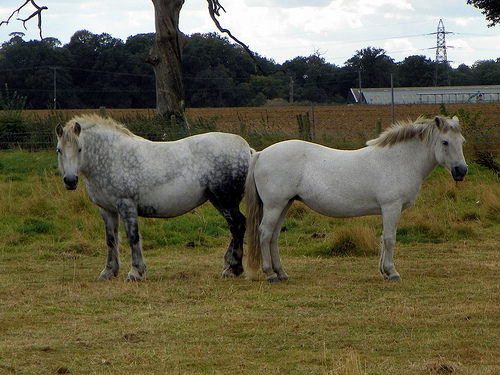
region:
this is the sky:
[379, 23, 400, 33]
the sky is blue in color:
[378, 20, 392, 32]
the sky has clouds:
[273, 10, 324, 59]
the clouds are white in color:
[258, 13, 288, 40]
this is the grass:
[104, 280, 219, 331]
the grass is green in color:
[141, 306, 211, 338]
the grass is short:
[165, 220, 188, 235]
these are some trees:
[195, 31, 407, 88]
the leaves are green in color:
[186, 43, 236, 85]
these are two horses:
[46, 117, 474, 350]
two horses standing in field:
[27, 63, 492, 374]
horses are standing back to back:
[25, 75, 485, 298]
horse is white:
[234, 105, 468, 288]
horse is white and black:
[42, 98, 249, 286]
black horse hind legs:
[189, 158, 258, 273]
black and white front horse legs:
[74, 183, 154, 285]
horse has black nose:
[57, 172, 82, 191]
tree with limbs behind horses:
[0, 8, 303, 263]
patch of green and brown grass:
[273, 195, 385, 269]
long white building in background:
[241, 48, 496, 122]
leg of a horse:
[100, 199, 127, 283]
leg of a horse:
[122, 203, 147, 280]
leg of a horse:
[221, 180, 248, 285]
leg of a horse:
[252, 192, 292, 284]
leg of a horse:
[375, 197, 407, 286]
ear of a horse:
[431, 110, 446, 134]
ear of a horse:
[67, 120, 84, 137]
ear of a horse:
[52, 118, 71, 140]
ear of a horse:
[448, 112, 460, 129]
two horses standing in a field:
[50, 92, 462, 307]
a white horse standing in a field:
[253, 111, 466, 276]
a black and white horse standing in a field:
[39, 103, 257, 288]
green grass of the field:
[211, 307, 358, 346]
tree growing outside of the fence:
[136, 0, 221, 120]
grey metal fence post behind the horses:
[305, 99, 322, 144]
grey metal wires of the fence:
[21, 62, 58, 147]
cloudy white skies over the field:
[288, 1, 359, 45]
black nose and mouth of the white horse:
[447, 158, 473, 188]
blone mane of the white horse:
[376, 119, 438, 146]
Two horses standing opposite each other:
[43, 113, 473, 292]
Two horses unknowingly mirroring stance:
[41, 100, 481, 309]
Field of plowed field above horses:
[13, 101, 495, 146]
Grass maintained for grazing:
[8, 164, 495, 365]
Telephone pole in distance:
[401, 18, 475, 98]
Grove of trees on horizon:
[0, 23, 491, 107]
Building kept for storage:
[338, 75, 498, 104]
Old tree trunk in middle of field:
[139, 0, 202, 137]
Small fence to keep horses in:
[0, 68, 490, 174]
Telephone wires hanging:
[6, 59, 393, 126]